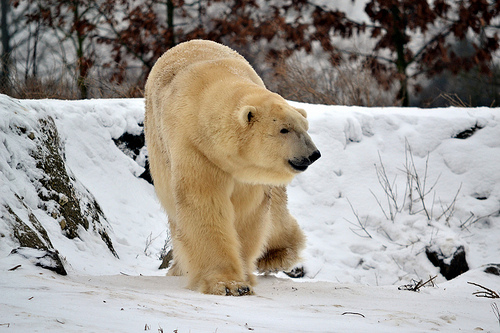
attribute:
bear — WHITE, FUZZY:
[134, 17, 327, 314]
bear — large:
[112, 39, 340, 301]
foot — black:
[185, 273, 255, 297]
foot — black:
[165, 262, 184, 276]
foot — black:
[245, 271, 256, 285]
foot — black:
[254, 247, 296, 272]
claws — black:
[225, 284, 250, 296]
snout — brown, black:
[285, 131, 321, 174]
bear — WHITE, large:
[139, 36, 322, 298]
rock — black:
[394, 237, 482, 302]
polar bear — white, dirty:
[125, 29, 380, 313]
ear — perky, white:
[235, 102, 265, 132]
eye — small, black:
[278, 126, 294, 139]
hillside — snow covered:
[322, 95, 490, 178]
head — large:
[231, 100, 302, 142]